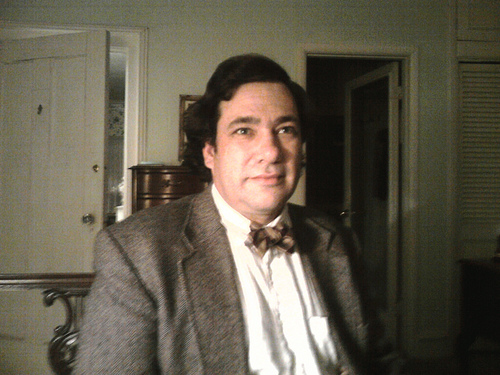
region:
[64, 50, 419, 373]
man in old fashioned brown suit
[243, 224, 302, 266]
brown and tan bow tie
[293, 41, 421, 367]
open door behind man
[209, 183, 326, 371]
white dress shirt with collar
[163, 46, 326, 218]
man with medium length brown hair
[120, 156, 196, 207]
small brown dresser with drawers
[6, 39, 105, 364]
white door with peep hole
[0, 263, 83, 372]
intricate bronze and brown chair back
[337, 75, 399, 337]
full panel glass front door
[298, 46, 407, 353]
dark room with open door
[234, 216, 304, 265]
brown bow tie on the man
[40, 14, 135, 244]
door cracked open behind the man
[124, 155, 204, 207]
small chest of drawers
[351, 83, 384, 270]
large mirror on the door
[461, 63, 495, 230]
louvers in the back of the room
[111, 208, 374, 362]
man wearing a grey suit coat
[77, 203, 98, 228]
door knob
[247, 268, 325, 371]
white shirt with pocket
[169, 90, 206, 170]
picture behind the man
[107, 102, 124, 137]
flowered wall paper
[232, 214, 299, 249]
bow tie on man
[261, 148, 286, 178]
nose of the man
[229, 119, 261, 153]
eye of the man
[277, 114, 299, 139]
eye of the man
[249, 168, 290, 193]
mouth of the man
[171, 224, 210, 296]
lapel of the jacket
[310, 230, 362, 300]
lapel of the jacket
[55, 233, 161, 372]
sleeve of the jacket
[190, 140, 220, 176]
ear of the man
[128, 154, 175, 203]
jewelry amorie in room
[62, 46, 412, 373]
A person sitting down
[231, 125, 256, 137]
The right eye of the person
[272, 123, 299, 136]
The left eye of the person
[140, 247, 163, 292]
Part of the gray jacket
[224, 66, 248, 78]
Part of the person's hair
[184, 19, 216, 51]
Part of the white wall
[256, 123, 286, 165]
The nose of the person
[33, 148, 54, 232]
Part of the white door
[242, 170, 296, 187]
The mouth of the person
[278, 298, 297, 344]
Part of the white shirt